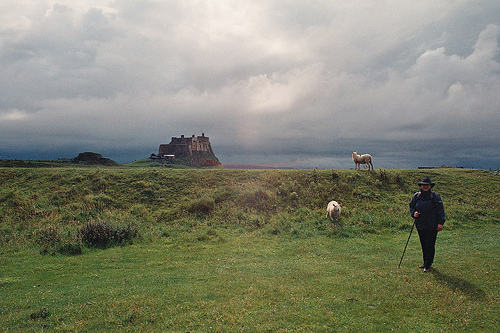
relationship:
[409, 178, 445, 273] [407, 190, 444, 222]
man wearing shirt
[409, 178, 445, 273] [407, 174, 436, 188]
man wearing hat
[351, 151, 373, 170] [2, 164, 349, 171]
lamb standing on pathway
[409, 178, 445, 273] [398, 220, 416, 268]
man has cane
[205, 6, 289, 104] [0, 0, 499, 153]
sun shining through cloud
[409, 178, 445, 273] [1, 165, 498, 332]
man in field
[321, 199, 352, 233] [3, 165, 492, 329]
lamb on hillside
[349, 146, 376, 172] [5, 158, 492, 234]
lamb on top of hill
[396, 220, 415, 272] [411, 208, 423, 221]
cane in hand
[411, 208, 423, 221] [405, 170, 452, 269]
hand of woman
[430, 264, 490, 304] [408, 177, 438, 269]
shadow of women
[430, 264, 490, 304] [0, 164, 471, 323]
shadow on grass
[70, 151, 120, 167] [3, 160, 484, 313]
hill in field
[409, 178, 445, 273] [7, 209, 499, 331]
man standing in field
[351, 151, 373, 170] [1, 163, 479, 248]
lamb standing on hill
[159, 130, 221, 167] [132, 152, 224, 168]
castle on top of hill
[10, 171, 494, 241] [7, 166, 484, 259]
hill covered in grass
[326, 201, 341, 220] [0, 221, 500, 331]
lamb in field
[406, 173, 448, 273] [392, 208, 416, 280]
man with cane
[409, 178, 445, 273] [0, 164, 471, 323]
man standing on grass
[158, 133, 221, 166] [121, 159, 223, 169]
castle on hill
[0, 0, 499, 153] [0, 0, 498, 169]
cloud in blue sky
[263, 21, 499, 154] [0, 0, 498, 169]
cloud in blue sky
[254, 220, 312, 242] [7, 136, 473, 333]
grass growing on embankment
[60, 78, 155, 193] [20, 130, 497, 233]
another hill farr in background